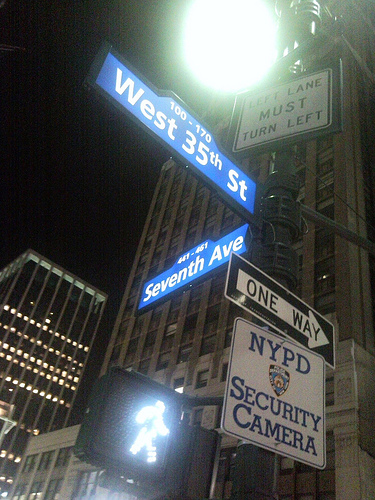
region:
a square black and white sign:
[217, 315, 325, 469]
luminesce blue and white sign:
[75, 380, 187, 474]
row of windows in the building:
[1, 303, 91, 355]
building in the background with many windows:
[1, 240, 109, 496]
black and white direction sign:
[222, 250, 334, 370]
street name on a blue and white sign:
[94, 52, 256, 214]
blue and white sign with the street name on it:
[138, 222, 249, 306]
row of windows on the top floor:
[21, 252, 106, 303]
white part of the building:
[147, 340, 227, 395]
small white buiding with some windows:
[7, 427, 78, 498]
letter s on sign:
[139, 280, 154, 302]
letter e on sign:
[150, 280, 161, 297]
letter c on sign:
[254, 386, 270, 414]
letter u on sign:
[269, 394, 282, 417]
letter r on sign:
[282, 398, 295, 430]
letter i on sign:
[292, 404, 301, 426]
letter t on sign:
[298, 407, 309, 428]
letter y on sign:
[311, 410, 322, 431]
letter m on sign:
[261, 417, 282, 442]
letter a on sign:
[307, 431, 316, 456]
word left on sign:
[243, 94, 283, 105]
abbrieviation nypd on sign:
[245, 330, 318, 375]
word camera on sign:
[224, 414, 321, 453]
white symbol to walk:
[132, 382, 175, 477]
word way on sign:
[287, 300, 328, 342]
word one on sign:
[241, 275, 289, 315]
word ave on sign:
[205, 231, 250, 265]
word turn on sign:
[233, 124, 281, 140]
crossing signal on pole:
[82, 366, 191, 484]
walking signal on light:
[131, 395, 168, 467]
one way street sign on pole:
[221, 261, 336, 358]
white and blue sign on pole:
[224, 316, 326, 466]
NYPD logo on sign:
[267, 361, 294, 397]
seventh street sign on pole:
[137, 227, 251, 311]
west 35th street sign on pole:
[100, 54, 264, 206]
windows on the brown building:
[11, 448, 62, 495]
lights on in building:
[11, 307, 29, 325]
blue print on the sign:
[242, 329, 314, 373]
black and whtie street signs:
[206, 259, 336, 474]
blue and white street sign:
[75, 49, 255, 224]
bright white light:
[150, 0, 285, 85]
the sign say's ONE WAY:
[223, 251, 336, 369]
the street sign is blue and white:
[136, 223, 247, 308]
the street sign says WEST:
[87, 39, 262, 224]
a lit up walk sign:
[63, 354, 198, 498]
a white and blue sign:
[213, 311, 341, 481]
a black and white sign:
[221, 251, 353, 361]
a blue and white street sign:
[57, 34, 273, 320]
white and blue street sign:
[57, 22, 349, 498]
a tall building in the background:
[70, 5, 370, 497]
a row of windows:
[105, 305, 226, 372]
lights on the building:
[0, 308, 92, 423]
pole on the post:
[298, 190, 373, 265]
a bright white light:
[162, 1, 298, 101]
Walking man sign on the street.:
[73, 365, 181, 479]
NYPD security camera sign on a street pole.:
[222, 315, 334, 470]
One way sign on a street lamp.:
[220, 249, 334, 368]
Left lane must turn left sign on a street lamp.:
[227, 63, 342, 159]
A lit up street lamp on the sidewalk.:
[179, 0, 330, 498]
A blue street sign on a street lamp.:
[82, 43, 260, 219]